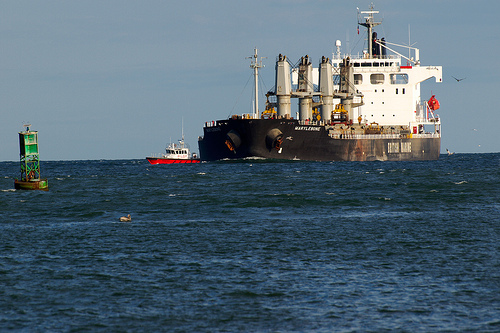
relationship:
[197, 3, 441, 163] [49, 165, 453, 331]
bigger boat in ocean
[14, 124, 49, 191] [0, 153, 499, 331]
buoy floating in ocean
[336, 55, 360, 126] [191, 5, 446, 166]
stacks on tanker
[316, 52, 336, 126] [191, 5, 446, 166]
stacks on tanker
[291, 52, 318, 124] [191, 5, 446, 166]
stacks on tanker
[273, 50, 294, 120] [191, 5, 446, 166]
stacks on tanker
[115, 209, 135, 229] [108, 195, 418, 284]
bird resting on ocean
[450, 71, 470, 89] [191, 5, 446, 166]
bird flying next to tanker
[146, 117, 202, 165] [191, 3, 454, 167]
boat on bigger boat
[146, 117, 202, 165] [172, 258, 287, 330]
boat on ocean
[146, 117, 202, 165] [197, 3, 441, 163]
boat next to bigger boat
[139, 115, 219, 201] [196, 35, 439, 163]
boat next to boat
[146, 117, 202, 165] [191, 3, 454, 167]
boat next to bigger boat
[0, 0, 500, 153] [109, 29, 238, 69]
sky has clouds